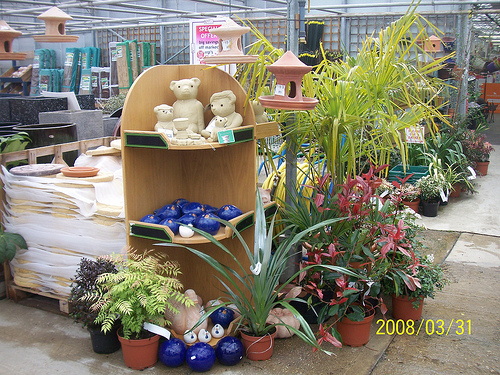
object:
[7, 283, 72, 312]
pallet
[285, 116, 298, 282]
pole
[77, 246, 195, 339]
plants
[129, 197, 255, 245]
display shelf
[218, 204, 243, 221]
pottery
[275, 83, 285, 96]
price tag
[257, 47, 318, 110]
bird feeder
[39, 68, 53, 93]
feeder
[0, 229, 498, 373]
ground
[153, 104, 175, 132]
bears